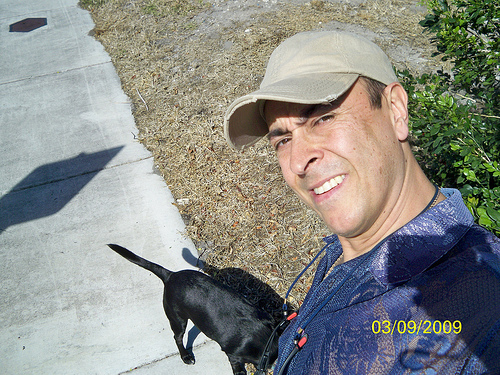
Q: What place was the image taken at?
A: It was taken at the street.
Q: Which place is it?
A: It is a street.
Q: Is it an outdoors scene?
A: Yes, it is outdoors.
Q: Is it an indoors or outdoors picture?
A: It is outdoors.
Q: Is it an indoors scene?
A: No, it is outdoors.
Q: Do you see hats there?
A: Yes, there is a hat.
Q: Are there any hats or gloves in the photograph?
A: Yes, there is a hat.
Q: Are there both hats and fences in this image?
A: No, there is a hat but no fences.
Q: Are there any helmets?
A: No, there are no helmets.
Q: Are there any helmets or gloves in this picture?
A: No, there are no helmets or gloves.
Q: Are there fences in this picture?
A: No, there are no fences.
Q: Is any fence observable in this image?
A: No, there are no fences.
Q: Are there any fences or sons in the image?
A: No, there are no fences or sons.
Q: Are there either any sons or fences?
A: No, there are no fences or sons.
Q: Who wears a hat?
A: The man wears a hat.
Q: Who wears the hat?
A: The man wears a hat.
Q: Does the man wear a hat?
A: Yes, the man wears a hat.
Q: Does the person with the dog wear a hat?
A: Yes, the man wears a hat.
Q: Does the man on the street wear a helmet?
A: No, the man wears a hat.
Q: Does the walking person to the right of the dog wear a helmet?
A: No, the man wears a hat.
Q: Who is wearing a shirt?
A: The man is wearing a shirt.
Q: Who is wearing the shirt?
A: The man is wearing a shirt.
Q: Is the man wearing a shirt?
A: Yes, the man is wearing a shirt.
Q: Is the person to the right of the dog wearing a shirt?
A: Yes, the man is wearing a shirt.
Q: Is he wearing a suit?
A: No, the man is wearing a shirt.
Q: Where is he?
A: The man is on the street.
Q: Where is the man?
A: The man is on the street.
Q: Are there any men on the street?
A: Yes, there is a man on the street.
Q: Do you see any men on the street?
A: Yes, there is a man on the street.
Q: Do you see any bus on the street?
A: No, there is a man on the street.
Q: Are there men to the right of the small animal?
A: Yes, there is a man to the right of the dog.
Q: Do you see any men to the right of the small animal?
A: Yes, there is a man to the right of the dog.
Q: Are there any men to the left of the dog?
A: No, the man is to the right of the dog.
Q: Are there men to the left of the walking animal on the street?
A: No, the man is to the right of the dog.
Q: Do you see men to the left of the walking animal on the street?
A: No, the man is to the right of the dog.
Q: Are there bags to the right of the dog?
A: No, there is a man to the right of the dog.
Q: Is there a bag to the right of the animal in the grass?
A: No, there is a man to the right of the dog.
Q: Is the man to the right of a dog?
A: Yes, the man is to the right of a dog.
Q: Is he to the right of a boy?
A: No, the man is to the right of a dog.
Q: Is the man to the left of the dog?
A: No, the man is to the right of the dog.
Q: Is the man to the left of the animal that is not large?
A: No, the man is to the right of the dog.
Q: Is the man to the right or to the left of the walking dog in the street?
A: The man is to the right of the dog.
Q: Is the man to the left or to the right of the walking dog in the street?
A: The man is to the right of the dog.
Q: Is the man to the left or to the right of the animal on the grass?
A: The man is to the right of the dog.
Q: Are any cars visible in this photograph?
A: No, there are no cars.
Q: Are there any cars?
A: No, there are no cars.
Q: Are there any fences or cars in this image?
A: No, there are no cars or fences.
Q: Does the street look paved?
A: Yes, the street is paved.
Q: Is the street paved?
A: Yes, the street is paved.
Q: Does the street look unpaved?
A: No, the street is paved.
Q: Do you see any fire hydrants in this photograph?
A: No, there are no fire hydrants.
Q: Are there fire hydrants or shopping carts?
A: No, there are no fire hydrants or shopping carts.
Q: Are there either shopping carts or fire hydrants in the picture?
A: No, there are no fire hydrants or shopping carts.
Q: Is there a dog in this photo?
A: Yes, there is a dog.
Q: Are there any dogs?
A: Yes, there is a dog.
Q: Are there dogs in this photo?
A: Yes, there is a dog.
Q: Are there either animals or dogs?
A: Yes, there is a dog.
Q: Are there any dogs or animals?
A: Yes, there is a dog.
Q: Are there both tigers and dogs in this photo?
A: No, there is a dog but no tigers.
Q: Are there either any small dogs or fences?
A: Yes, there is a small dog.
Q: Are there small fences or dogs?
A: Yes, there is a small dog.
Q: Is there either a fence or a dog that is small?
A: Yes, the dog is small.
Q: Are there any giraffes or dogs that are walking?
A: Yes, the dog is walking.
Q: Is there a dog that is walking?
A: Yes, there is a dog that is walking.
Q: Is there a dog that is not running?
A: Yes, there is a dog that is walking.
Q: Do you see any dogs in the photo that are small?
A: Yes, there is a small dog.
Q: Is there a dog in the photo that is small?
A: Yes, there is a dog that is small.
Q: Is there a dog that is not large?
A: Yes, there is a small dog.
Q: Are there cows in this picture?
A: No, there are no cows.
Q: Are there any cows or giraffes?
A: No, there are no cows or giraffes.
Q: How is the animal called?
A: The animal is a dog.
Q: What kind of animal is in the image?
A: The animal is a dog.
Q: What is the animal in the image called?
A: The animal is a dog.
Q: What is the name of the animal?
A: The animal is a dog.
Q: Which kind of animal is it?
A: The animal is a dog.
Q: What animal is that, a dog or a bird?
A: That is a dog.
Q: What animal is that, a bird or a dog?
A: That is a dog.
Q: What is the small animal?
A: The animal is a dog.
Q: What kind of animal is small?
A: The animal is a dog.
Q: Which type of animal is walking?
A: The animal is a dog.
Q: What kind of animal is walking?
A: The animal is a dog.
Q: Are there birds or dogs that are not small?
A: No, there is a dog but it is small.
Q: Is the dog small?
A: Yes, the dog is small.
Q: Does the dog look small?
A: Yes, the dog is small.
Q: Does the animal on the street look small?
A: Yes, the dog is small.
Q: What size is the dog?
A: The dog is small.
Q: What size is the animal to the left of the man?
A: The dog is small.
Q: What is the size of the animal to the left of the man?
A: The dog is small.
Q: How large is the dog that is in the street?
A: The dog is small.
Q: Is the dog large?
A: No, the dog is small.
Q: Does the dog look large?
A: No, the dog is small.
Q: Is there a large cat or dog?
A: No, there is a dog but it is small.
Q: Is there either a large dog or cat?
A: No, there is a dog but it is small.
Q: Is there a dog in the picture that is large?
A: No, there is a dog but it is small.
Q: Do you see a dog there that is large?
A: No, there is a dog but it is small.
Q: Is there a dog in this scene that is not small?
A: No, there is a dog but it is small.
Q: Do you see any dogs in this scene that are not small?
A: No, there is a dog but it is small.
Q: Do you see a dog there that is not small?
A: No, there is a dog but it is small.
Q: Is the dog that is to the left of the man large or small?
A: The dog is small.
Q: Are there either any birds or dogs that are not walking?
A: No, there is a dog but it is walking.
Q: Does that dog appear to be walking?
A: Yes, the dog is walking.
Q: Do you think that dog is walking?
A: Yes, the dog is walking.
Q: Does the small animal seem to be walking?
A: Yes, the dog is walking.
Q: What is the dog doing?
A: The dog is walking.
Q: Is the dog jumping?
A: No, the dog is walking.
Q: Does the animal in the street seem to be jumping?
A: No, the dog is walking.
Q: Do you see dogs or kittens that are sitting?
A: No, there is a dog but it is walking.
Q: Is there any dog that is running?
A: No, there is a dog but it is walking.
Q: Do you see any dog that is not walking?
A: No, there is a dog but it is walking.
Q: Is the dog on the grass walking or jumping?
A: The dog is walking.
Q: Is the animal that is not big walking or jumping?
A: The dog is walking.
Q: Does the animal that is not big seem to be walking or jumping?
A: The dog is walking.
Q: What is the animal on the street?
A: The animal is a dog.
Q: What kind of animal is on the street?
A: The animal is a dog.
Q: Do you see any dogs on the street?
A: Yes, there is a dog on the street.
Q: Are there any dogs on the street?
A: Yes, there is a dog on the street.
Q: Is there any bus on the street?
A: No, there is a dog on the street.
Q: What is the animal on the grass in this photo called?
A: The animal is a dog.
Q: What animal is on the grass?
A: The animal is a dog.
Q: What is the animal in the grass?
A: The animal is a dog.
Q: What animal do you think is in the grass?
A: The animal is a dog.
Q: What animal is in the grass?
A: The animal is a dog.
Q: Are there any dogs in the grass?
A: Yes, there is a dog in the grass.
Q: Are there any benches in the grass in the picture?
A: No, there is a dog in the grass.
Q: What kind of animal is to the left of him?
A: The animal is a dog.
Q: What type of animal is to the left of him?
A: The animal is a dog.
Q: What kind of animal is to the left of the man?
A: The animal is a dog.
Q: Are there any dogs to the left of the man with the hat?
A: Yes, there is a dog to the left of the man.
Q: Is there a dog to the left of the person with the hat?
A: Yes, there is a dog to the left of the man.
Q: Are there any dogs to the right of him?
A: No, the dog is to the left of the man.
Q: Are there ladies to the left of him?
A: No, there is a dog to the left of the man.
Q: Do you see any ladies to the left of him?
A: No, there is a dog to the left of the man.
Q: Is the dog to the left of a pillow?
A: No, the dog is to the left of a man.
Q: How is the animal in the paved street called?
A: The animal is a dog.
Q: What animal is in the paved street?
A: The animal is a dog.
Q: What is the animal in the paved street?
A: The animal is a dog.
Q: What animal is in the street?
A: The animal is a dog.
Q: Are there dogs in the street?
A: Yes, there is a dog in the street.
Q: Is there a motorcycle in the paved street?
A: No, there is a dog in the street.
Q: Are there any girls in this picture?
A: No, there are no girls.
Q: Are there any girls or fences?
A: No, there are no girls or fences.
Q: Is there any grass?
A: Yes, there is grass.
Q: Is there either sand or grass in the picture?
A: Yes, there is grass.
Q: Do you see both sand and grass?
A: No, there is grass but no sand.